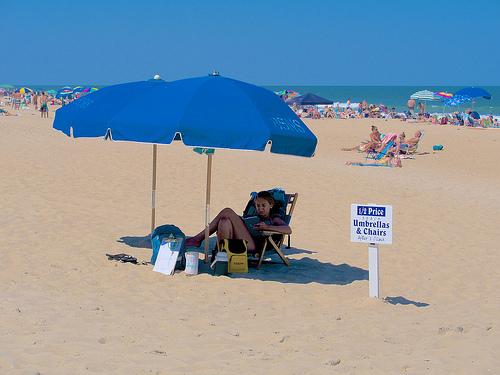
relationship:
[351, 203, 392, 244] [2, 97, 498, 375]
sign on beach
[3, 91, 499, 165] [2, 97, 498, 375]
people are on beach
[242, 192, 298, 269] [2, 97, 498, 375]
chair on beach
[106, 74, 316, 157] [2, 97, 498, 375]
canopy on beach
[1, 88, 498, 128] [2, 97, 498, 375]
families are on beach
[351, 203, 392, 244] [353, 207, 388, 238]
sign has writing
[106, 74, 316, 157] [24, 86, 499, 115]
canopy close to ocean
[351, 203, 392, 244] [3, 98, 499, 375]
sign in sand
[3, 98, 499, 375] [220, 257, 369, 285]
sand has a shadow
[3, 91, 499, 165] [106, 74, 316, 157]
people are using canopy